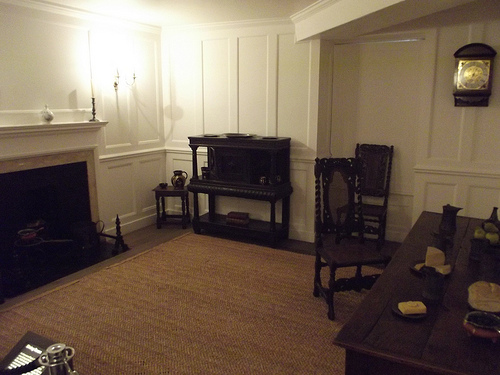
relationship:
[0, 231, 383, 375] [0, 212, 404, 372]
carpet on floor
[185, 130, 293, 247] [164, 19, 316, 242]
wooden hutch lining wall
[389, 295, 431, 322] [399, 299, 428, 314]
dish of butter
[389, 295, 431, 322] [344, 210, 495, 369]
dish on table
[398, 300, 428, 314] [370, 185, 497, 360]
butter on table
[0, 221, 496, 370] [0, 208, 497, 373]
carpet on floor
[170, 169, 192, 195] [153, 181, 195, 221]
picture on table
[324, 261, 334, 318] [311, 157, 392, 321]
leg of chair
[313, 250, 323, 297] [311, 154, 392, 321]
leg of chair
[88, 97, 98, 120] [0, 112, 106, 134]
candle holder sitting on mantle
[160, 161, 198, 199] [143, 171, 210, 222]
jug sitting on table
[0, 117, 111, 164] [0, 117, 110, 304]
mantle above fireplace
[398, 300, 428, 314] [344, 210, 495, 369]
butter on table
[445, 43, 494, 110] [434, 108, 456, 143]
clock on wall